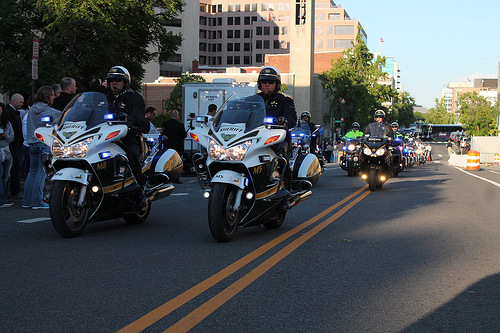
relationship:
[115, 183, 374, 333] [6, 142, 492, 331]
line on ground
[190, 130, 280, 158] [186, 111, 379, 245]
lights on bike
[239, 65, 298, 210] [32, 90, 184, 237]
officer riding bike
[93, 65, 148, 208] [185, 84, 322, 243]
officer riding bike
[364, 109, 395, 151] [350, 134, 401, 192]
officer riding bike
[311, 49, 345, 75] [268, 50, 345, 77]
red bricks on wall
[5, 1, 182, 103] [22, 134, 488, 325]
tree in street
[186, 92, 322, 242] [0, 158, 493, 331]
bike on road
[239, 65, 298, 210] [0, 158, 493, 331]
officer on road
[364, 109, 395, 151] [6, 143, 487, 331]
officer on side of street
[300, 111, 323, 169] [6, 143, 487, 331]
officer on side of street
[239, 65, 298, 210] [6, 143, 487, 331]
officer on side of street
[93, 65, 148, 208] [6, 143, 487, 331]
officer on side of street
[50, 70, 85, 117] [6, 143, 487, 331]
people on side of street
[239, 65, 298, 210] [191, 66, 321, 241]
officer riding a motorcycles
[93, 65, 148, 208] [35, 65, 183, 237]
officer riding a motorcycles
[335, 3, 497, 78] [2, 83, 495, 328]
sky behind cityscape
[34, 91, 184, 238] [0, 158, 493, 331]
bike on road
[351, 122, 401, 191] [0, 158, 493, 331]
bike on road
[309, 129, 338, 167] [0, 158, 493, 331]
motorcycle on road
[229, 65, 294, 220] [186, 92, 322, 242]
officer on bike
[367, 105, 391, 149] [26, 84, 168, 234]
officer on motorcycle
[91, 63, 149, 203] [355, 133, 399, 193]
officer on motorcycle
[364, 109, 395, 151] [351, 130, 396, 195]
officer on motorcycle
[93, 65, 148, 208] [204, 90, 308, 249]
officer on motorcycle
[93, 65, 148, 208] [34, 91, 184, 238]
officer on bike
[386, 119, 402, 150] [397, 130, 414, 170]
officer on motorcycle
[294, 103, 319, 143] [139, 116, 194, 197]
officer on motorcycle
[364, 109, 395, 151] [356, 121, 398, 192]
officer on motorcycle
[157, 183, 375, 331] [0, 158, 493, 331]
line on road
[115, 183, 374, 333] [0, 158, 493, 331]
line on road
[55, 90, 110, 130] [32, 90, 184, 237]
windshield on bike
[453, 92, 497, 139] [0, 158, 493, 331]
tree along side road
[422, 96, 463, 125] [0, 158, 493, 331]
tree along side road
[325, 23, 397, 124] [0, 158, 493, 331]
tree along side road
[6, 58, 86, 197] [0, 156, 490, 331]
people standing on roadside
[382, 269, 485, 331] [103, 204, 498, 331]
shadow on ground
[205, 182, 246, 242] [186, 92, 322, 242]
wheel of bike